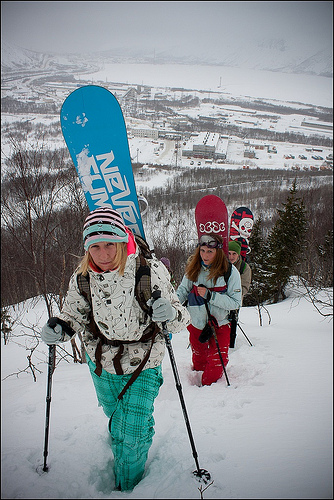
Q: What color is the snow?
A: White.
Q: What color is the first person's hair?
A: Blonde.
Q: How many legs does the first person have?
A: 2.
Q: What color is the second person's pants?
A: Red.